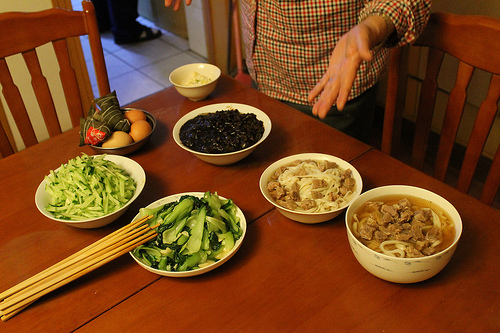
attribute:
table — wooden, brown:
[271, 256, 351, 323]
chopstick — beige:
[30, 238, 188, 285]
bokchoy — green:
[129, 206, 244, 291]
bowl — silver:
[142, 111, 379, 201]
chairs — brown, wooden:
[25, 9, 473, 114]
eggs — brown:
[100, 122, 152, 143]